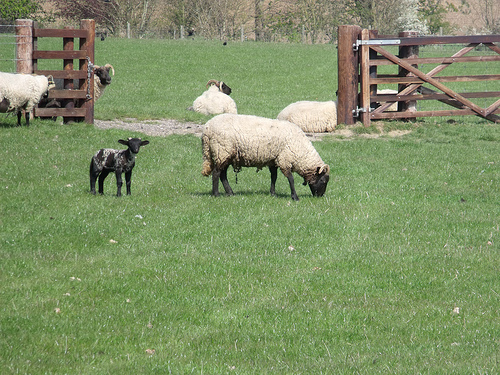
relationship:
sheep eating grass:
[198, 111, 330, 203] [1, 35, 498, 373]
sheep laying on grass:
[274, 98, 336, 133] [1, 35, 498, 373]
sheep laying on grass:
[192, 78, 239, 115] [1, 35, 498, 373]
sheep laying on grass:
[375, 89, 398, 113] [1, 35, 498, 373]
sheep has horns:
[92, 63, 114, 102] [91, 64, 117, 77]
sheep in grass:
[198, 111, 330, 203] [1, 35, 498, 373]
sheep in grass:
[87, 137, 150, 195] [1, 35, 498, 373]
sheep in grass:
[1, 70, 54, 126] [1, 35, 498, 373]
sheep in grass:
[92, 63, 114, 102] [1, 35, 498, 373]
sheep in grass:
[192, 78, 239, 115] [1, 35, 498, 373]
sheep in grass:
[274, 98, 336, 133] [1, 35, 498, 373]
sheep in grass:
[375, 89, 398, 113] [1, 35, 498, 373]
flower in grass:
[450, 304, 465, 319] [1, 35, 498, 373]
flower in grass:
[286, 242, 298, 256] [1, 35, 498, 373]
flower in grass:
[53, 305, 65, 315] [1, 35, 498, 373]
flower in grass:
[107, 235, 119, 247] [1, 35, 498, 373]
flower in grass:
[62, 180, 75, 192] [1, 35, 498, 373]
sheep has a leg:
[198, 111, 330, 203] [285, 171, 300, 205]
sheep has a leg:
[198, 111, 330, 203] [266, 164, 278, 196]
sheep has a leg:
[198, 111, 330, 203] [221, 172, 236, 198]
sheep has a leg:
[198, 111, 330, 203] [210, 164, 225, 197]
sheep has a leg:
[1, 70, 54, 126] [24, 108, 32, 126]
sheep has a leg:
[1, 70, 54, 126] [17, 105, 24, 128]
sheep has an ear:
[198, 111, 330, 203] [317, 164, 329, 175]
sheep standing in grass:
[87, 137, 150, 195] [1, 35, 498, 373]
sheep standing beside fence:
[92, 63, 114, 102] [17, 19, 96, 130]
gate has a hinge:
[360, 26, 499, 125] [350, 106, 374, 118]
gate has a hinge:
[360, 26, 499, 125] [351, 38, 402, 50]